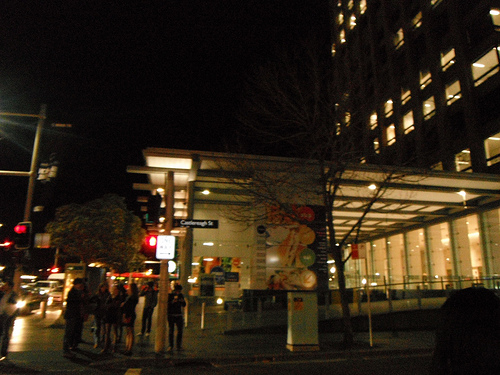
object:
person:
[122, 281, 141, 358]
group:
[60, 270, 141, 360]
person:
[109, 283, 126, 352]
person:
[92, 282, 113, 353]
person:
[58, 274, 86, 363]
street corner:
[3, 326, 163, 369]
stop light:
[143, 233, 159, 248]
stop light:
[12, 222, 27, 239]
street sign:
[169, 217, 220, 230]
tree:
[208, 29, 443, 348]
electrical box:
[285, 287, 323, 352]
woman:
[164, 283, 189, 354]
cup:
[173, 295, 179, 303]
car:
[10, 280, 43, 316]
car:
[32, 278, 58, 300]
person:
[141, 278, 157, 334]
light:
[464, 231, 483, 243]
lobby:
[332, 201, 499, 295]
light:
[439, 235, 450, 246]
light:
[416, 231, 424, 239]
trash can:
[38, 300, 48, 319]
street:
[1, 265, 74, 320]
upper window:
[332, 1, 341, 8]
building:
[310, 2, 499, 319]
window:
[381, 121, 398, 150]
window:
[401, 113, 414, 132]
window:
[417, 94, 438, 123]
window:
[439, 76, 465, 111]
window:
[462, 44, 499, 86]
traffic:
[1, 256, 63, 314]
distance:
[0, 255, 195, 319]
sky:
[1, 3, 340, 259]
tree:
[45, 192, 148, 308]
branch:
[340, 158, 430, 250]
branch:
[231, 173, 320, 236]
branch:
[231, 112, 298, 146]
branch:
[304, 42, 328, 128]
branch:
[279, 52, 312, 123]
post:
[155, 167, 174, 360]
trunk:
[321, 208, 358, 348]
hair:
[114, 282, 126, 297]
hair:
[130, 282, 140, 307]